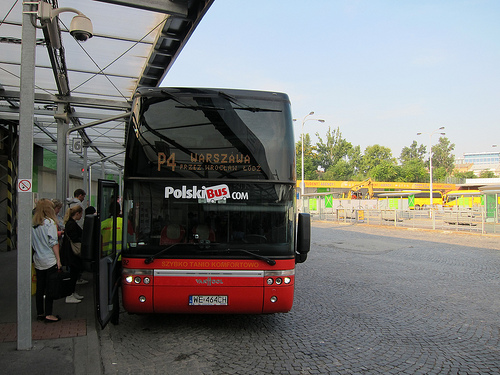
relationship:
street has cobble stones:
[102, 215, 499, 372] [100, 218, 499, 371]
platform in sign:
[34, 229, 101, 374] [70, 139, 83, 156]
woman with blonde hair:
[31, 196, 69, 321] [32, 193, 54, 231]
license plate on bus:
[188, 293, 228, 305] [121, 87, 309, 311]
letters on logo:
[221, 183, 253, 210] [144, 143, 271, 233]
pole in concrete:
[14, 3, 40, 353] [0, 270, 103, 370]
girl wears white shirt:
[33, 196, 66, 326] [32, 215, 57, 272]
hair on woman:
[62, 200, 87, 224] [56, 198, 83, 308]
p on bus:
[155, 150, 165, 170] [94, 84, 312, 329]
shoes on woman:
[28, 298, 76, 325] [14, 191, 85, 340]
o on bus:
[174, 188, 181, 198] [94, 84, 312, 329]